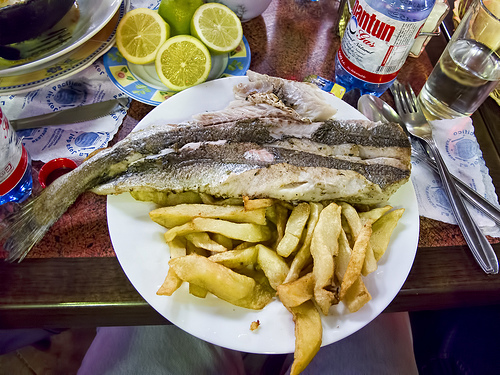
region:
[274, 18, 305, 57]
this is a table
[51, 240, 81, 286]
the table is wooden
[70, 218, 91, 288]
the table is brown in color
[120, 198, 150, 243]
this is a plate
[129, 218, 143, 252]
the plate is white in color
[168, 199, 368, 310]
these are French fries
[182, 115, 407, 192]
this is fried fish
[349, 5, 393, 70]
this is a bottle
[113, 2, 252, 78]
these are some fruits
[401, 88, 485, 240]
this is a fork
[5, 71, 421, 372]
A plate of fish and fries.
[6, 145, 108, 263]
The tail of the fish.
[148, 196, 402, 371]
Browned crispy fries.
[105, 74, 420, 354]
A round white plate.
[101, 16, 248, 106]
Sliced limes on a small plate.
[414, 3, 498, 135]
Clear liquid in a clear glass.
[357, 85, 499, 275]
Spoon and fork on top of a white napkin.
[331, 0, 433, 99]
Blue bottle with a white and red label.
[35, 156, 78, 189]
A red bottle cap on top of the table.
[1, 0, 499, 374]
Food and drinks on top of a wooden table.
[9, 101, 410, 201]
fish on white plate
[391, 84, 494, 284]
silver fork on table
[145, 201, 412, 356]
french fries on white table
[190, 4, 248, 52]
green lime on table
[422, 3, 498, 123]
clear glass on table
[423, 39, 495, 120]
water in the glass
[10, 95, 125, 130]
silver knife on table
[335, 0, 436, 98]
blue bottle on the table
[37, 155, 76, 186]
red top of bottle on table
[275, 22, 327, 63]
wood table in room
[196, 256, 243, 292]
potato chips on a plate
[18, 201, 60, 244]
the tail of a fish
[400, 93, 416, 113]
an eating fork on the table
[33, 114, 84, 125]
knife on the table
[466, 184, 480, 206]
a spoon on the table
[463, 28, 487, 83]
a glass on the table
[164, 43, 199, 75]
lemon on a saucer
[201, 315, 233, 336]
a white plate with food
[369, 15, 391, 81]
a bottle on the table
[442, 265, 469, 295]
a table with lots of things on it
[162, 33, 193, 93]
Yellow half of lemon.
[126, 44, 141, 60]
Yellow lemon cut in half.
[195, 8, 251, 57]
Green lime cut in half.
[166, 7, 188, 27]
Green lime cut in half.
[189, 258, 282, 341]
French fry sitting on plate.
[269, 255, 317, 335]
French fry sitting on plate.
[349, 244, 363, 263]
French fry sitting on plate.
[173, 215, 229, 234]
French fry sitting on plate.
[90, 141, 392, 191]
Large piece of fish sitting on plate.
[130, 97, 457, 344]
Round white plate sitting on table.